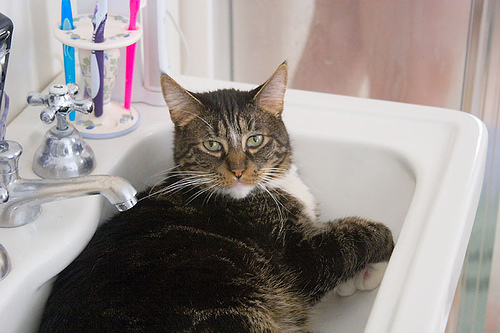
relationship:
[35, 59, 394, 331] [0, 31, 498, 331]
cat on sink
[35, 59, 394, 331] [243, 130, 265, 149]
cat has eye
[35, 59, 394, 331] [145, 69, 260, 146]
cat has ear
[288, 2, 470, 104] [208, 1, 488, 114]
person standing in shower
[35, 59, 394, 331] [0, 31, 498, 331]
cat in sink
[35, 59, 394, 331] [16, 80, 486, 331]
cat in sink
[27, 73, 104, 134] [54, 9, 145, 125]
handle next to holder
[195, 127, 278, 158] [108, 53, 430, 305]
eyes of cat